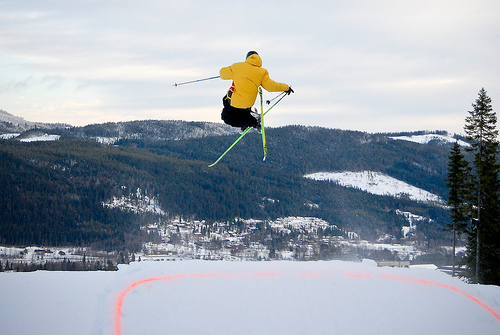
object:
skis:
[257, 87, 267, 162]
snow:
[0, 248, 500, 335]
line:
[110, 272, 499, 334]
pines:
[462, 90, 498, 284]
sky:
[0, 0, 174, 118]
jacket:
[218, 54, 290, 109]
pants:
[221, 95, 257, 128]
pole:
[174, 75, 221, 87]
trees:
[446, 142, 480, 286]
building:
[408, 264, 438, 270]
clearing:
[302, 170, 443, 201]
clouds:
[298, 0, 500, 89]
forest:
[0, 117, 451, 262]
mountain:
[0, 110, 499, 233]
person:
[220, 50, 295, 134]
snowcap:
[385, 133, 470, 148]